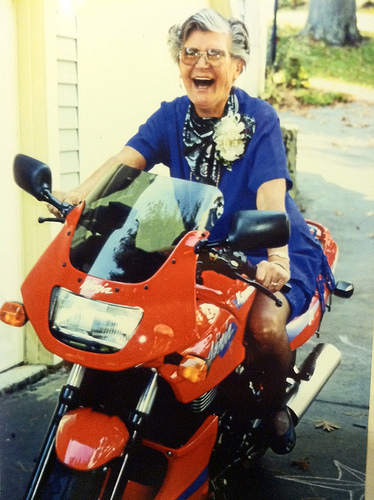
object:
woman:
[45, 8, 338, 454]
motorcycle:
[0, 153, 354, 497]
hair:
[167, 7, 250, 71]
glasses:
[177, 46, 233, 67]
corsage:
[212, 112, 246, 163]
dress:
[125, 87, 336, 324]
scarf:
[182, 89, 258, 237]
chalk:
[275, 458, 365, 500]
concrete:
[0, 98, 373, 499]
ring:
[269, 279, 279, 287]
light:
[47, 283, 143, 355]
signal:
[176, 353, 207, 385]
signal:
[0, 301, 27, 327]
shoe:
[255, 389, 297, 454]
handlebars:
[196, 240, 292, 308]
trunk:
[295, 0, 369, 48]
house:
[0, 0, 270, 373]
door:
[75, 0, 209, 185]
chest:
[169, 147, 248, 241]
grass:
[264, 21, 374, 105]